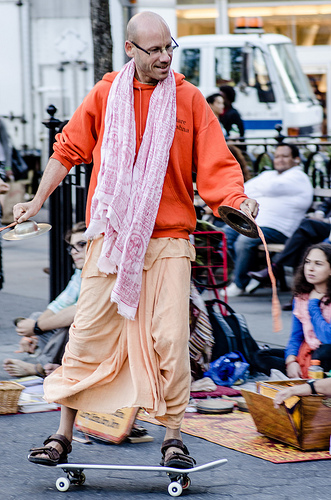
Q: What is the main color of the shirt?
A: Orange.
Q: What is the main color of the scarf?
A: Pink.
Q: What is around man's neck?
A: Scarf.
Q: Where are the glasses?
A: On man's eyes.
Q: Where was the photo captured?
A: City park.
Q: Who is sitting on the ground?
A: A young girl.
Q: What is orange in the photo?
A: Sweatshirt.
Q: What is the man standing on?
A: A skateboard.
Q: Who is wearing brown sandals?
A: Man on skateboard.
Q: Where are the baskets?
A: On the sidewalk.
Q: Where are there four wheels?
A: Bottom of skateboard.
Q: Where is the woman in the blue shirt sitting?
A: On the ground.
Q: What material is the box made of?
A: Wood.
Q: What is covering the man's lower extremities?
A: A skirt.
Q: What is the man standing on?
A: A skateboard.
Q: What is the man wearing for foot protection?
A: Sandals.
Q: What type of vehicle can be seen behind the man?
A: A truck.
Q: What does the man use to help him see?
A: Glasses.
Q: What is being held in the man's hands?
A: Cymbals.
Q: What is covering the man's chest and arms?
A: A sweatshirt.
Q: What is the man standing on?
A: A skateboard.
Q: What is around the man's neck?
A: A scarf.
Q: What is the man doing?
A: Skateboarding.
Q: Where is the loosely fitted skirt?
A: On the man.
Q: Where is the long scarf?
A: The man's neck.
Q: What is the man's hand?
A: Cymbals.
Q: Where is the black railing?
A: Behind the sitting man.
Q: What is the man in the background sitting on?
A: A bench.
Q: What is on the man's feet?
A: Slippers.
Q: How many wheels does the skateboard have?
A: Four.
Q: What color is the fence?
A: Black.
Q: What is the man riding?
A: A skateboard.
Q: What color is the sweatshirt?
A: Orange.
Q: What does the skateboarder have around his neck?
A: A scarf.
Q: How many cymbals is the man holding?
A: Two.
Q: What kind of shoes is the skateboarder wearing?
A: Sandals.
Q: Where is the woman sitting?
A: On the ground.